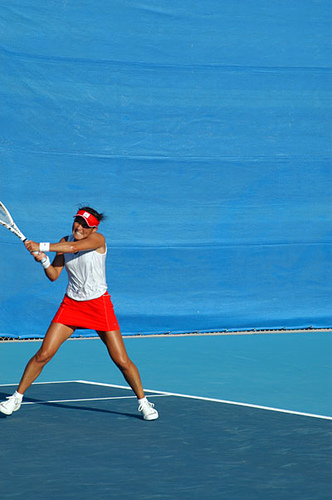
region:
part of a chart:
[120, 31, 153, 77]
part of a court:
[187, 434, 208, 469]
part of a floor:
[206, 411, 232, 448]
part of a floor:
[201, 407, 226, 461]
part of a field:
[210, 442, 234, 478]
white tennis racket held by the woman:
[0, 203, 48, 260]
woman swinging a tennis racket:
[0, 196, 168, 422]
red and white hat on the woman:
[70, 207, 98, 230]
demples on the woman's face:
[69, 226, 88, 237]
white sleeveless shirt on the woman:
[58, 235, 109, 307]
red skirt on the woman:
[47, 289, 121, 334]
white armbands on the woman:
[37, 239, 57, 275]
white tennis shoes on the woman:
[0, 393, 164, 424]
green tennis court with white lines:
[0, 325, 331, 499]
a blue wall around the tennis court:
[0, 0, 331, 341]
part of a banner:
[154, 138, 195, 209]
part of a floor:
[181, 443, 209, 488]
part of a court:
[220, 445, 255, 492]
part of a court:
[198, 461, 223, 490]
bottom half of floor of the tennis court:
[0, 418, 331, 499]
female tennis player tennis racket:
[0, 200, 25, 239]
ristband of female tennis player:
[38, 240, 46, 250]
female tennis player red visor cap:
[71, 209, 97, 226]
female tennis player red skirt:
[54, 299, 114, 326]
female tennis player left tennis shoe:
[137, 398, 157, 417]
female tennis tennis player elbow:
[43, 269, 58, 279]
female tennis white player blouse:
[64, 253, 105, 293]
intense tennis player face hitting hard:
[72, 219, 84, 236]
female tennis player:
[0, 201, 160, 419]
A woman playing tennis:
[7, 180, 184, 432]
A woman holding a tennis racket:
[7, 193, 196, 440]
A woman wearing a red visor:
[25, 198, 176, 441]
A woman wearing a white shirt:
[26, 193, 161, 447]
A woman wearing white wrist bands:
[32, 218, 166, 440]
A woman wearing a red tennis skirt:
[29, 210, 193, 440]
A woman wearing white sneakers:
[17, 204, 181, 446]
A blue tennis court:
[52, 359, 323, 473]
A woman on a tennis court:
[20, 197, 165, 453]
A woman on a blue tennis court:
[15, 185, 203, 442]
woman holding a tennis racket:
[0, 198, 161, 419]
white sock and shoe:
[135, 395, 159, 422]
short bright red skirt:
[49, 291, 121, 333]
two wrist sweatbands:
[37, 240, 52, 269]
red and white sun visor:
[72, 208, 99, 228]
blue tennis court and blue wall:
[0, 0, 329, 498]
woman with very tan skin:
[0, 199, 160, 419]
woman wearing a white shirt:
[0, 197, 158, 421]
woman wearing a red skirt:
[0, 197, 158, 418]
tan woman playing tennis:
[0, 199, 159, 421]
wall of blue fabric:
[0, 1, 330, 341]